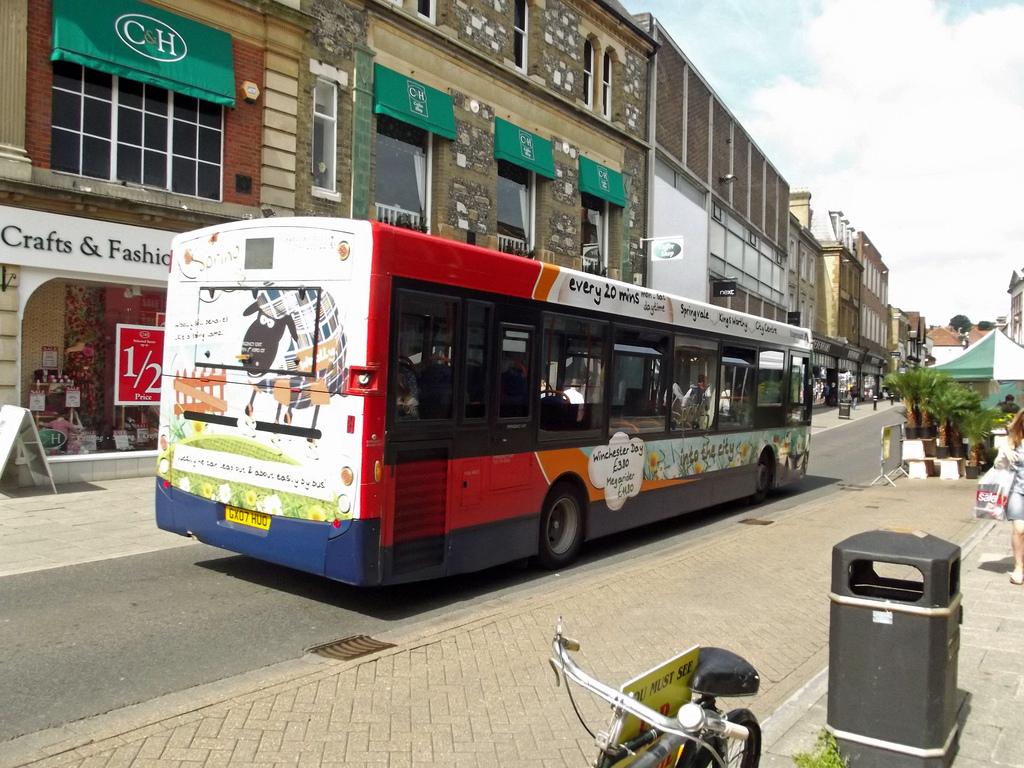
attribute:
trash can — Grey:
[805, 527, 967, 763]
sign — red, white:
[100, 311, 159, 417]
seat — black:
[682, 618, 780, 688]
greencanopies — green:
[51, 8, 630, 225]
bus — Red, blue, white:
[156, 219, 817, 587]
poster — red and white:
[114, 326, 165, 404]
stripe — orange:
[542, 304, 666, 438]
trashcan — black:
[829, 526, 960, 765]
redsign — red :
[112, 324, 158, 405]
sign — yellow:
[613, 640, 704, 747]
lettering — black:
[563, 267, 803, 347]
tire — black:
[535, 481, 596, 572]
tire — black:
[760, 453, 789, 503]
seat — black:
[684, 639, 758, 702]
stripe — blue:
[142, 466, 812, 607]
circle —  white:
[665, 670, 728, 768]